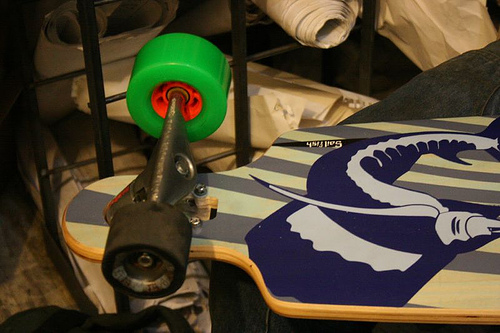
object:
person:
[206, 0, 499, 333]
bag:
[0, 303, 193, 331]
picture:
[247, 114, 499, 306]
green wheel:
[121, 32, 232, 143]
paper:
[254, 0, 368, 51]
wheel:
[98, 200, 193, 298]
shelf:
[0, 0, 379, 332]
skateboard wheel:
[102, 200, 192, 300]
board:
[52, 117, 499, 320]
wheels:
[126, 31, 236, 138]